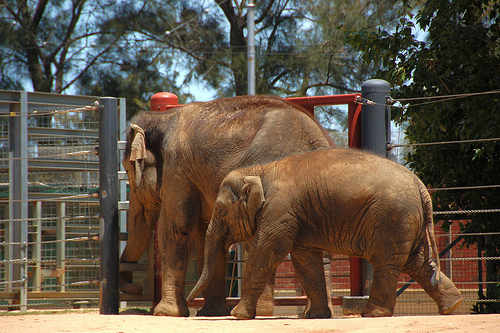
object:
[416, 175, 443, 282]
tail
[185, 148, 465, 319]
elephant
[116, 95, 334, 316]
elephant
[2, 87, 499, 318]
enclosure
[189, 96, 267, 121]
hair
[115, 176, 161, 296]
trunk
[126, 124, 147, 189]
ear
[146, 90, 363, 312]
gate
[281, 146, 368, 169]
hair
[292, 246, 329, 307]
leg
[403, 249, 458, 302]
leg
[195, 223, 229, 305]
leg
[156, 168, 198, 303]
leg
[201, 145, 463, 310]
sand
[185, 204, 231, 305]
trunk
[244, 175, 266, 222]
ear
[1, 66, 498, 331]
pen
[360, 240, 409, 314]
leg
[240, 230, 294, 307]
leg